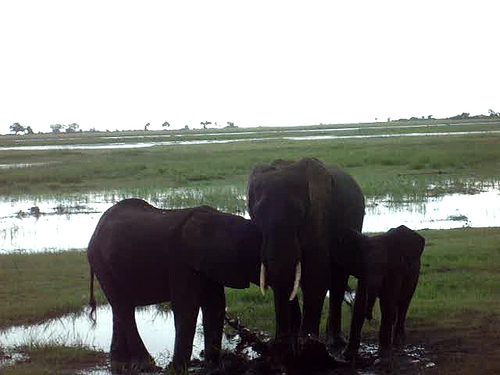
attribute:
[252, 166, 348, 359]
elephant — gray, large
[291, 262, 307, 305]
tusk — white, large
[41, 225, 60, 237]
water — calm, gray, clear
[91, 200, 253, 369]
elephant — gray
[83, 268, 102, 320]
tail — gray, long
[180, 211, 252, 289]
ear — gray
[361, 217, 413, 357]
elephant — small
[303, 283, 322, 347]
leg — gray, green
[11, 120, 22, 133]
tree — green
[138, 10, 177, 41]
sky — cloudy, clear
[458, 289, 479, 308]
grass — green, short